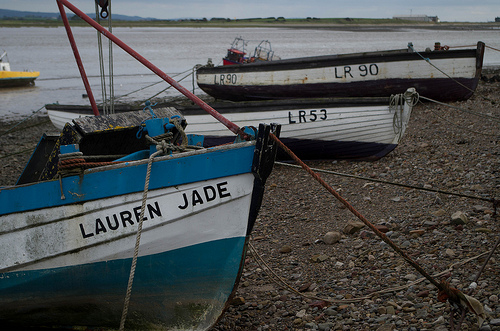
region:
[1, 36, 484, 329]
the boats on land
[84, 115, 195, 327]
the rope hanging off of the boat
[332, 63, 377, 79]
the LR 90 on the boat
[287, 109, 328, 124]
the LR53 on the boat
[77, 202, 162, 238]
the word LAUREN on the boat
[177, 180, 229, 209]
the word JADE on the boat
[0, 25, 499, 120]
the body of water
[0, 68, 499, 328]
the rocks on the ground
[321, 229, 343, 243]
the rock on the ground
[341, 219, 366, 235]
the rock on the ground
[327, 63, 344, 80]
The letter is black.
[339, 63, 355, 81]
The letter is black.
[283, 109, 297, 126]
The letter is black.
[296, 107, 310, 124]
The letter is black.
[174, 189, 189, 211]
The letter is black.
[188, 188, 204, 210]
The letter is black.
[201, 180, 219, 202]
The letter is black.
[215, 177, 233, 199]
The letter is black.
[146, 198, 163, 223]
The letter is black.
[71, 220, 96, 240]
The letter is black.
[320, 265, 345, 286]
rocks on the beach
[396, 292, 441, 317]
grommot on the jacket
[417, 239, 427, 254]
grommot on the jacket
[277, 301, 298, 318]
grommot on the jacket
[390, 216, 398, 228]
grommot on the jacket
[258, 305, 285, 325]
grommot on the jacket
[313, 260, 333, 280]
grommot on the jacket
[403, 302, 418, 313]
grommot on the jacket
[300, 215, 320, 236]
grommot on the jacket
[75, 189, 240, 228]
name on the boat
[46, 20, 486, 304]
boats on the land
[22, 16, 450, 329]
boats out of the water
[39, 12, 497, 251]
three boats on land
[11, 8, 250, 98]
a body of water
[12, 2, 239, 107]
a calm body of water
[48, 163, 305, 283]
lauren jade boat on land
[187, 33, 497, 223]
small boats on land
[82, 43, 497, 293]
small boats tied up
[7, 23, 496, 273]
three small boats on land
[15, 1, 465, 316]
land with three small boats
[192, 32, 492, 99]
boat docked on shore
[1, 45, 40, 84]
boat in the water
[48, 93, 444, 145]
boat docked on shore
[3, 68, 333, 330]
boat docked on shore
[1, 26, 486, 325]
boats docked on the shore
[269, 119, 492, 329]
red rope attached to boat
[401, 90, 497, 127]
rope attached to boat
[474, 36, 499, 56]
rope attached to boat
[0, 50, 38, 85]
yellow boat in water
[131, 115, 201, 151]
rope holder on boat